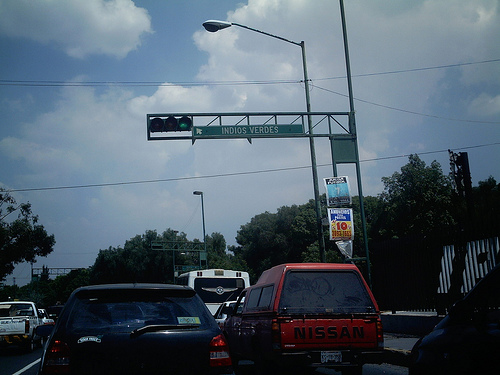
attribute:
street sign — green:
[195, 123, 309, 135]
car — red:
[239, 260, 384, 365]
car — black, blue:
[41, 286, 228, 372]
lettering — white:
[443, 245, 497, 289]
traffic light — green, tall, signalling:
[147, 116, 201, 136]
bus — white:
[192, 269, 248, 296]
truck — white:
[0, 297, 44, 347]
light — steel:
[176, 114, 195, 134]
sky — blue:
[152, 18, 190, 71]